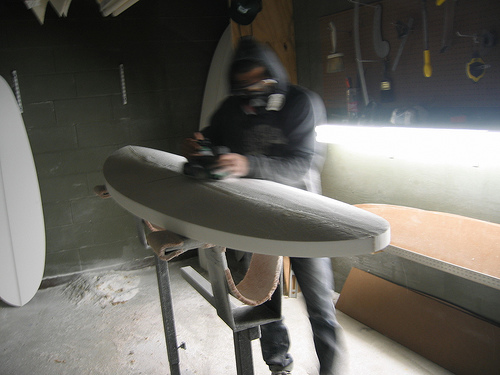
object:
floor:
[1, 264, 446, 373]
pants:
[258, 256, 345, 375]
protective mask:
[230, 79, 285, 116]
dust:
[60, 270, 139, 309]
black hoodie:
[183, 35, 315, 194]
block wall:
[2, 10, 110, 278]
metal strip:
[119, 64, 127, 105]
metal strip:
[12, 70, 23, 114]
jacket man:
[186, 35, 347, 375]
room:
[0, 1, 500, 375]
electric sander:
[183, 139, 230, 180]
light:
[312, 123, 500, 159]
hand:
[208, 152, 249, 179]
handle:
[423, 50, 433, 77]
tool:
[380, 61, 393, 103]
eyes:
[239, 77, 272, 84]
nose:
[249, 78, 263, 92]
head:
[228, 36, 293, 95]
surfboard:
[101, 144, 390, 258]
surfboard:
[0, 74, 47, 308]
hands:
[179, 133, 204, 157]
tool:
[327, 22, 345, 73]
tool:
[422, 0, 433, 77]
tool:
[465, 51, 488, 82]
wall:
[291, 2, 497, 122]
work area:
[36, 127, 494, 374]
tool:
[353, 0, 384, 105]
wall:
[44, 25, 190, 115]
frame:
[146, 229, 282, 374]